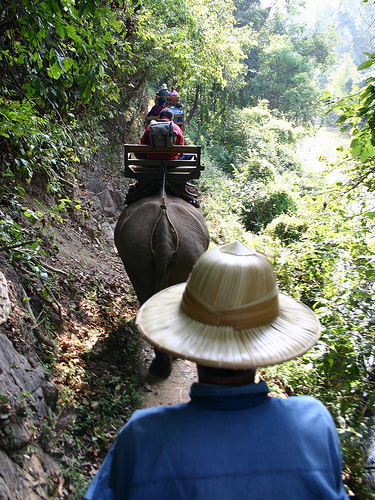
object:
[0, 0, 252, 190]
foliage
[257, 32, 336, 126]
trees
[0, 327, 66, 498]
stone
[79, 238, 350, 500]
person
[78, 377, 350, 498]
shirt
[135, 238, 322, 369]
hat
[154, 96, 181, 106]
seat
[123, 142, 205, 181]
bench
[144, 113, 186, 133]
bench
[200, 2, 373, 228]
jungle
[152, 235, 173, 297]
tail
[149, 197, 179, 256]
collar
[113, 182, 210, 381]
elephant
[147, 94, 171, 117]
people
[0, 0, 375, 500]
ground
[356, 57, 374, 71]
leaf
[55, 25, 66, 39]
leaf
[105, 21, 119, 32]
leaf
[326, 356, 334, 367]
leaf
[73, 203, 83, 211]
leaf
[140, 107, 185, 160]
people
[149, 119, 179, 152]
backpack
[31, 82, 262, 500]
path